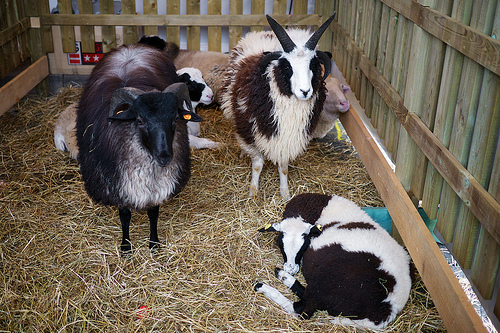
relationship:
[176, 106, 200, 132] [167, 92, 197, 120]
tag attached to ear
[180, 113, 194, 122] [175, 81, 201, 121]
tag attached to ear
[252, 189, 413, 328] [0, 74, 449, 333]
goat sleeping on hay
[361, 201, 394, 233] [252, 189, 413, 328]
fabric under goat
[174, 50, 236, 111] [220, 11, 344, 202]
sheep behind goat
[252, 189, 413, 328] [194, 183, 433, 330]
goat lying on ground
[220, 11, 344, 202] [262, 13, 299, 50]
goat has horn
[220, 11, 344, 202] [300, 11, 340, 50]
goat has horn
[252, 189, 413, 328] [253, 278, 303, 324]
goat has leg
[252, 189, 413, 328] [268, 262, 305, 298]
goat has leg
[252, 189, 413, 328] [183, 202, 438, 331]
goat laying on ground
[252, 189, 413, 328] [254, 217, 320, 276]
goat has head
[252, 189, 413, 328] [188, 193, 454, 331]
goat lying on ground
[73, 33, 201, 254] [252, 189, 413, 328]
ram standing next to goat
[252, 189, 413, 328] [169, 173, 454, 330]
goat laying on ground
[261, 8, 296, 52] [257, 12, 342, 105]
horn on goat's head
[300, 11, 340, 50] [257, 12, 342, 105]
horn on goat's head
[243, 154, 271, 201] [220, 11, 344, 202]
leg on goat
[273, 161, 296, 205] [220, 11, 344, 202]
leg on goat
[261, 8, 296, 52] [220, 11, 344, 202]
horn on goat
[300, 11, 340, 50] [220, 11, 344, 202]
horn on goat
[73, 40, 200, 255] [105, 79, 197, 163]
ram has head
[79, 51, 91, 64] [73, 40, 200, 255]
star behind ram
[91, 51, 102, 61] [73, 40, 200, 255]
star behind ram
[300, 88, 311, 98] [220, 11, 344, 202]
nose on goat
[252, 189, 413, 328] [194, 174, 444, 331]
goat lying in hay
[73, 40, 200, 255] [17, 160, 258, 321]
ram standing in hay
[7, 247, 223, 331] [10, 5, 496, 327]
hay in stall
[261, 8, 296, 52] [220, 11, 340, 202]
horn on goat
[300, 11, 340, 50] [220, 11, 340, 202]
horn on goat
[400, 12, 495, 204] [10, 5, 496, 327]
wall in stall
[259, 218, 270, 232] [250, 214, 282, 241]
tag on sheep's ear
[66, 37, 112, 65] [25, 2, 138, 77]
sticker on wall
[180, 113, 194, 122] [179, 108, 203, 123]
tag on ear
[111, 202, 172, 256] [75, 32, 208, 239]
legs are attached to ram